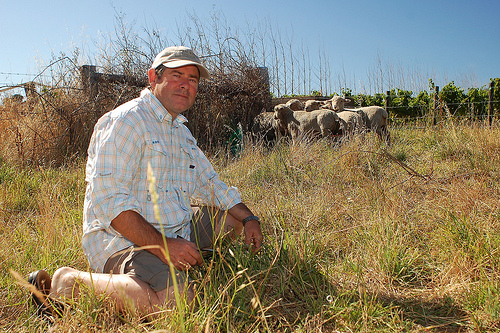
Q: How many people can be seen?
A: 1.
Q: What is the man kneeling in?
A: Grass.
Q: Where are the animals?
A: Behind the man.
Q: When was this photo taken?
A: Daytime.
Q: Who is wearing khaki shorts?
A: Man.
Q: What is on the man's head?
A: Khaki hat.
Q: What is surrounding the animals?
A: Fence.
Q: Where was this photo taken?
A: In a pasture.